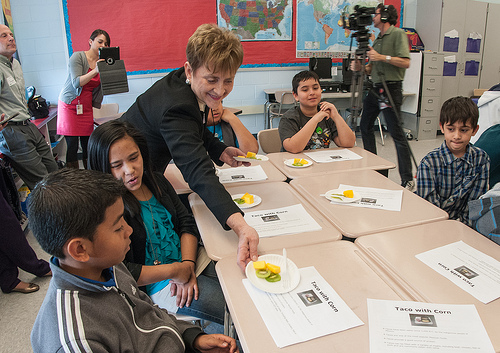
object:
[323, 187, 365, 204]
plate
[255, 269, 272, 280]
kiwi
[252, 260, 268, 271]
pineapple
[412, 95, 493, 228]
child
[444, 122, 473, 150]
face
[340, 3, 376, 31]
camera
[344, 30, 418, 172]
tripod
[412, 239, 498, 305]
paper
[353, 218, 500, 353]
table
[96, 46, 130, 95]
ipad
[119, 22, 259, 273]
lady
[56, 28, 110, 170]
lady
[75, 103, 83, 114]
name tag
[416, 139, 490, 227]
shirt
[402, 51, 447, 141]
cabinet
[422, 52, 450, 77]
drawer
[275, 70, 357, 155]
kid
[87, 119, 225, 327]
girl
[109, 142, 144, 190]
face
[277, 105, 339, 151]
t-shirt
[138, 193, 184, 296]
shirt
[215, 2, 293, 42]
wall map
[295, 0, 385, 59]
wall map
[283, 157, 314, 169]
plate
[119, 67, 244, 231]
suit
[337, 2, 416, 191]
cameraman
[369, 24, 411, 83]
shirt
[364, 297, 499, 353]
paper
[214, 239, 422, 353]
table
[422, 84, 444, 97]
drawer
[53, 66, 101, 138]
dress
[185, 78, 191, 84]
earring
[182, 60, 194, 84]
ear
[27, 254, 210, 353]
jacket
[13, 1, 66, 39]
wall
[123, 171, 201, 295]
sweater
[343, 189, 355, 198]
pineapple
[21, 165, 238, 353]
boy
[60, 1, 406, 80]
board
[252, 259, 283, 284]
kiwi and pineapple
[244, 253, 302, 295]
plate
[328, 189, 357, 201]
kiwi and pineapple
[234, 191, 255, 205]
kiwi and pineapple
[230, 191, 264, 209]
plate